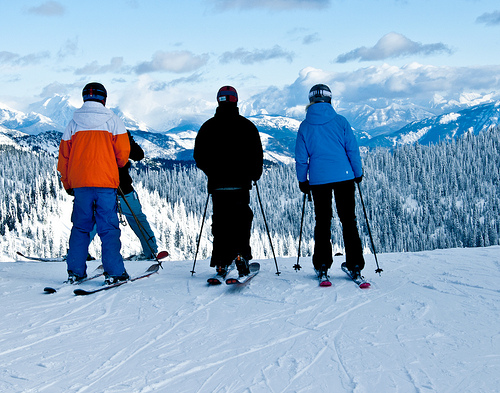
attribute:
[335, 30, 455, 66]
cloud — white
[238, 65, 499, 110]
cloud — white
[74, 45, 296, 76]
cloud — white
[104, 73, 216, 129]
cloud — white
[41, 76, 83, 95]
cloud — white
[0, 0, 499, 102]
sky — blue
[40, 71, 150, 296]
man — white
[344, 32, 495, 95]
clouds — white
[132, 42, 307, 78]
clouds — white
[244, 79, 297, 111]
clouds — white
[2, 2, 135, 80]
clouds — white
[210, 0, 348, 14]
clouds — white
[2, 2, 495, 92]
sky — blue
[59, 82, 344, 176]
people — skiing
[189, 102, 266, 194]
jacket — black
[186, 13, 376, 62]
sky — blue, clear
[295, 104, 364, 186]
jacket — blue, ski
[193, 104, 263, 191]
jacket — ski, black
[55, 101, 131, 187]
jacket — ski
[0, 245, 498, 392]
snow — white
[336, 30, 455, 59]
clouds — white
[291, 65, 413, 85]
clouds — white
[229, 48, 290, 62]
clouds — white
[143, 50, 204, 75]
clouds — white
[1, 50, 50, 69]
clouds — white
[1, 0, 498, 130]
sky — blue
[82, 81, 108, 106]
helmet — back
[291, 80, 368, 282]
skier — preparing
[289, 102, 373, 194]
jacket — blue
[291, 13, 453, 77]
sky — blue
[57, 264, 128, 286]
feet — person's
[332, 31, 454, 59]
cloud — fluffy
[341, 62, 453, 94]
cloud — fluffy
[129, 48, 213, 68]
cloud — fluffy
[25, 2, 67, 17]
cloud — fluffy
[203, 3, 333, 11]
cloud — fluffy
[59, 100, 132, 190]
jacket — orange, white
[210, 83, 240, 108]
helmet — back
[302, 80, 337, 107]
helmet — back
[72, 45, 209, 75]
clouds — white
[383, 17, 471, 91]
clouds — white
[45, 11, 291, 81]
sky — blue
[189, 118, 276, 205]
ski jacket — black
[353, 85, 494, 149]
mountains — distance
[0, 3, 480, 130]
clouds — white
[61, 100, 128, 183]
jacket — orange